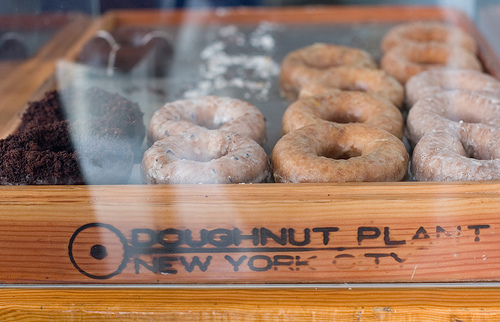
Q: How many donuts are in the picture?
A: 13.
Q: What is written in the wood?
A: Doughnut Plant New York City.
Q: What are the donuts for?
A: To be sold.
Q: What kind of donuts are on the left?
A: Chocolate.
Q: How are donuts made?
A: Dough is fried.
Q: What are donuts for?
A: To be eaten.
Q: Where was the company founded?
A: New York City.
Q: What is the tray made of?
A: Wood.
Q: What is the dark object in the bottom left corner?
A: Donut.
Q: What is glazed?
A: Donut.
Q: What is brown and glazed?
A: Donut.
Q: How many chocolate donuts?
A: 2.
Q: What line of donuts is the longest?
A: Far right.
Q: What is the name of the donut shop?
A: Doughnut Plant.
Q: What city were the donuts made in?
A: New York City.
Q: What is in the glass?
A: Reflection.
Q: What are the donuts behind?
A: Glass.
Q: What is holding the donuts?
A: A wood rack.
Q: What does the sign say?
A: Doughnut Plant New York City.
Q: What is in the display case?
A: Doughnuts.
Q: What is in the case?
A: 4 different types of doughnuts.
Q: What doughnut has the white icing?
A: The chocolate doughnut.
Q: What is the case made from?
A: Wood.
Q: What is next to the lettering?
A: A circle with a dot.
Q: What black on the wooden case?
A: The lettering.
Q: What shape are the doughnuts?
A: Round.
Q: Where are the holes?
A: In doughnuts.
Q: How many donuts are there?
A: Fourteen.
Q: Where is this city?
A: New York city.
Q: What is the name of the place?
A: Doughnut plant.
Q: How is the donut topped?
A: Chocolate glazed.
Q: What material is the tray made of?
A: Wood.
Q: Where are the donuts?
A: Under glass.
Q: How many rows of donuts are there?
A: Four.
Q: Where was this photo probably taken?
A: In bakery.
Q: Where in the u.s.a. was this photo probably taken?
A: New york city.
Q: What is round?
A: Donuts.